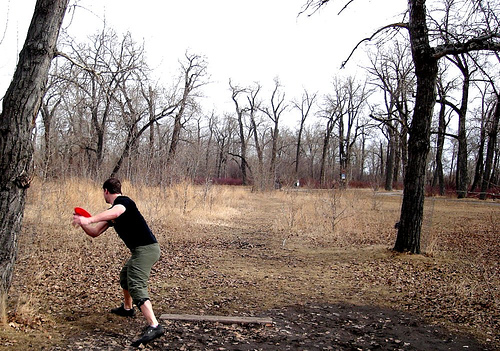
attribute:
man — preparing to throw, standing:
[72, 179, 163, 345]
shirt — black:
[110, 197, 156, 250]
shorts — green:
[118, 242, 161, 297]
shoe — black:
[110, 304, 131, 316]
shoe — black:
[140, 325, 163, 340]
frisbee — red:
[74, 207, 88, 219]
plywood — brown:
[159, 313, 272, 327]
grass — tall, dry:
[28, 174, 192, 224]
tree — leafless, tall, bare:
[299, 2, 497, 253]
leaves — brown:
[42, 250, 117, 304]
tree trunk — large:
[0, 1, 67, 275]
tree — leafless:
[261, 80, 282, 182]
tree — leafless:
[228, 80, 250, 163]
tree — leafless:
[164, 51, 199, 174]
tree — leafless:
[116, 92, 174, 189]